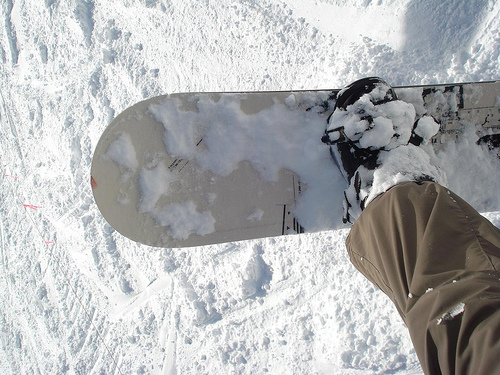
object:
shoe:
[321, 77, 439, 224]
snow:
[326, 78, 438, 207]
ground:
[0, 0, 500, 375]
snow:
[1, 3, 498, 374]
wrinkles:
[346, 183, 500, 375]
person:
[322, 77, 500, 375]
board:
[91, 79, 500, 248]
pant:
[345, 180, 500, 375]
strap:
[321, 115, 440, 145]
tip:
[91, 92, 187, 248]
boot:
[325, 76, 439, 212]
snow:
[107, 86, 500, 246]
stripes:
[282, 85, 464, 234]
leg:
[345, 181, 500, 375]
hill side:
[1, 0, 498, 372]